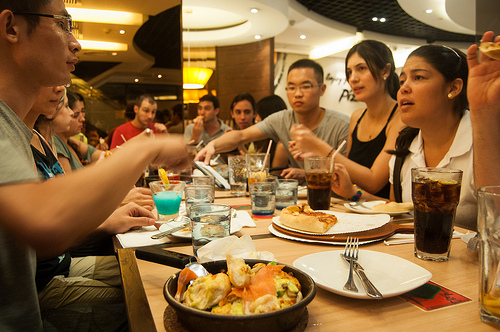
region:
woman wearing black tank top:
[328, 38, 401, 200]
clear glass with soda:
[407, 154, 458, 259]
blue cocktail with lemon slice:
[147, 168, 183, 215]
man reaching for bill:
[197, 48, 330, 182]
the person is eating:
[0, 8, 207, 325]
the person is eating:
[386, 30, 488, 242]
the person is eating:
[309, 29, 421, 214]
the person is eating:
[219, 89, 260, 144]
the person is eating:
[171, 89, 248, 164]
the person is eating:
[55, 85, 117, 177]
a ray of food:
[154, 245, 345, 315]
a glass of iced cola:
[400, 165, 469, 263]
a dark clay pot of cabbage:
[161, 253, 321, 330]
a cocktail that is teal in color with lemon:
[144, 168, 187, 228]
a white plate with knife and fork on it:
[286, 233, 440, 309]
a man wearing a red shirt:
[107, 91, 172, 166]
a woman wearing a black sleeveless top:
[285, 37, 408, 224]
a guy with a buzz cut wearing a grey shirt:
[197, 55, 369, 195]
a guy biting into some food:
[178, 91, 237, 166]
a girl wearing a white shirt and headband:
[392, 42, 489, 229]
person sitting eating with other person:
[382, 42, 474, 229]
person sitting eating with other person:
[2, 2, 195, 329]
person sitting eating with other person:
[468, 29, 498, 211]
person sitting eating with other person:
[282, 37, 403, 197]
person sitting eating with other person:
[189, 55, 350, 182]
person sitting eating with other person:
[230, 97, 255, 158]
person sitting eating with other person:
[251, 94, 296, 176]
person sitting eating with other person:
[184, 93, 241, 163]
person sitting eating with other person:
[107, 96, 180, 186]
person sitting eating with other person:
[49, 89, 113, 175]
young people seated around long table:
[8, 12, 485, 324]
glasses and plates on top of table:
[124, 135, 496, 327]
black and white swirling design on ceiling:
[184, 2, 495, 57]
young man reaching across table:
[188, 55, 350, 185]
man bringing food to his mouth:
[184, 94, 227, 154]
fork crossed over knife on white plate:
[296, 237, 428, 305]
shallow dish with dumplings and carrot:
[167, 255, 317, 320]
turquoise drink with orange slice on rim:
[146, 164, 186, 223]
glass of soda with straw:
[300, 137, 347, 209]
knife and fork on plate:
[304, 214, 378, 329]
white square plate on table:
[280, 237, 437, 316]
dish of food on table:
[151, 240, 319, 330]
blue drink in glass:
[143, 169, 190, 221]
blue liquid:
[157, 190, 179, 208]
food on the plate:
[181, 260, 288, 319]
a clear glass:
[472, 184, 498, 300]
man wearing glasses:
[51, 11, 78, 34]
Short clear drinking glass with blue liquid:
[146, 180, 188, 222]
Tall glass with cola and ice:
[408, 164, 464, 262]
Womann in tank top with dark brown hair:
[290, 35, 405, 195]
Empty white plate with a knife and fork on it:
[291, 235, 433, 300]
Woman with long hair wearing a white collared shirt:
[387, 43, 478, 235]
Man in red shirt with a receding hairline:
[108, 92, 168, 151]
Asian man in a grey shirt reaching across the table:
[192, 56, 352, 178]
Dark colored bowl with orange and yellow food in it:
[162, 250, 316, 329]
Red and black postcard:
[402, 277, 474, 313]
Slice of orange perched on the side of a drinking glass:
[158, 165, 173, 186]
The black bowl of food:
[164, 251, 316, 324]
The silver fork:
[332, 230, 360, 313]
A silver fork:
[334, 225, 358, 297]